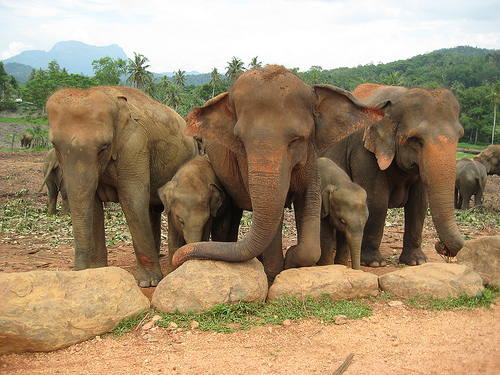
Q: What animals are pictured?
A: Elephants.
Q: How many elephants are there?
A: 9 elephants.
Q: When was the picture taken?
A: During the daytime.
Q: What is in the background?
A: Trees.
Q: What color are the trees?
A: Green.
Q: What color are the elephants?
A: Grey.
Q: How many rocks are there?
A: 5 rocks.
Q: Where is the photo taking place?
A: At an animal refuge.